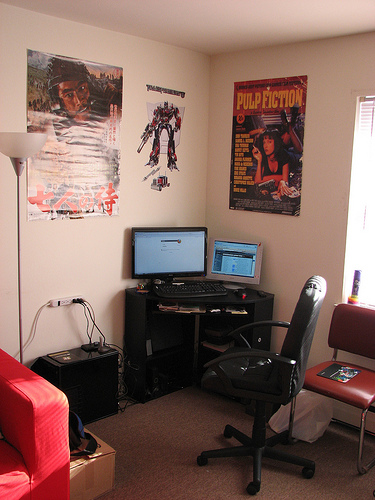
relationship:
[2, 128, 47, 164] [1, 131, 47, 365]
shade on lamp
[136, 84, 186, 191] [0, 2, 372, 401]
poster on wall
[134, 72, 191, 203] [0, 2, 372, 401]
poster on wall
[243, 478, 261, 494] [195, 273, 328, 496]
wheel on chair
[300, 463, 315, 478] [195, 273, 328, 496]
wheel on chair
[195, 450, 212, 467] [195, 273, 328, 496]
wheel on chair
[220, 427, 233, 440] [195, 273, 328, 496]
wheel on chair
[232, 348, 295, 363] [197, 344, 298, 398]
arm on chair